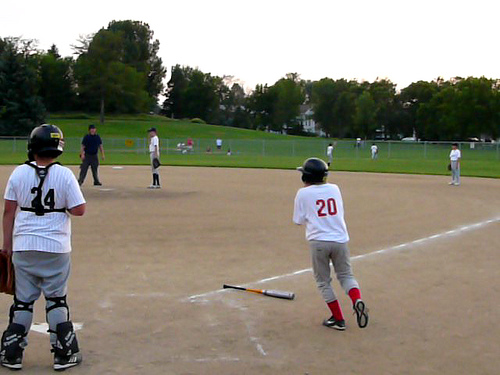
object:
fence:
[1, 132, 498, 167]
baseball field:
[3, 140, 496, 372]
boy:
[0, 122, 85, 371]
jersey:
[291, 182, 352, 245]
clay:
[1, 164, 500, 373]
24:
[30, 187, 56, 207]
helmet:
[25, 122, 66, 163]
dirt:
[2, 175, 497, 373]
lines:
[191, 216, 493, 295]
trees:
[163, 64, 200, 122]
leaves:
[1, 34, 19, 52]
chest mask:
[18, 160, 70, 215]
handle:
[222, 283, 248, 292]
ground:
[0, 165, 500, 373]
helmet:
[296, 156, 331, 184]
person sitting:
[185, 136, 195, 153]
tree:
[67, 19, 165, 124]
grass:
[346, 139, 496, 175]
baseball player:
[288, 158, 373, 333]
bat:
[217, 281, 297, 301]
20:
[314, 198, 338, 217]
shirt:
[4, 162, 87, 256]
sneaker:
[323, 315, 346, 330]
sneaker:
[352, 298, 369, 329]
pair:
[319, 297, 369, 331]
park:
[6, 108, 484, 168]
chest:
[12, 171, 73, 210]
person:
[186, 138, 193, 152]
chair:
[178, 140, 194, 154]